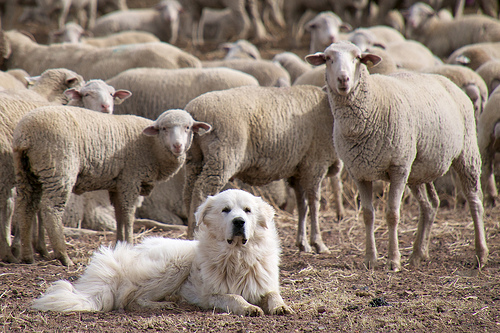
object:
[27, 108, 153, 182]
wool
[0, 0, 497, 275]
herd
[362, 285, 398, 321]
slot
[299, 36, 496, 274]
sheep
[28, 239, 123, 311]
dog's tail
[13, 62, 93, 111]
sheep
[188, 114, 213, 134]
ear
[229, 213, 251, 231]
nose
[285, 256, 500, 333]
grass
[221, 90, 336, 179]
wool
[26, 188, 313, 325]
dog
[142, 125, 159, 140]
ear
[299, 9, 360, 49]
sheep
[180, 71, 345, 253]
sheep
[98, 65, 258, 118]
sheep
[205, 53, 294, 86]
sheep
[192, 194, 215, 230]
ear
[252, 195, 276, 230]
ear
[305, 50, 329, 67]
ear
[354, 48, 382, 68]
ear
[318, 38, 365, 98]
head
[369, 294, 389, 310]
feces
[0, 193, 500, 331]
ground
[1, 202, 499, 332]
dirt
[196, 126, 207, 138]
tag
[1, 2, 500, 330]
kennel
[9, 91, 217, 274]
sheep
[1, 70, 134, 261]
sheep